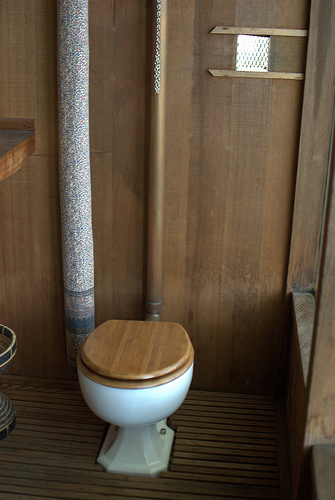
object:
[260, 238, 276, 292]
brown color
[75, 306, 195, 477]
one toilet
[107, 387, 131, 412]
white color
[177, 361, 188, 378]
seat is brown color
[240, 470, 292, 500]
floor is brown color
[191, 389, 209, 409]
made of wood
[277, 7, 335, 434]
window is brown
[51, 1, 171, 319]
two pipe is running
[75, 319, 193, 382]
this is a toilet lid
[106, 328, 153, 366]
lid is brown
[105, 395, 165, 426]
toilet is white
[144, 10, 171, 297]
pipe is brown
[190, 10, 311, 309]
this is a wall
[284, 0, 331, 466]
this is a window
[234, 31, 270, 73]
small glass window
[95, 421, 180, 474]
porcelain base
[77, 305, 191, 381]
toilet seat top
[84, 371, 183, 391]
brown wood panels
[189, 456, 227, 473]
brown wood panels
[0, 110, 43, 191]
wooden shelf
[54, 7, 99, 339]
pipe for tiolet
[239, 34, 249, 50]
window above tiolet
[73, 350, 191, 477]
bowl is white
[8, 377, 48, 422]
this is the floor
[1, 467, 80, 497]
floor is wooden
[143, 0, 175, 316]
this is a pipe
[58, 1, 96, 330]
pipe is metallic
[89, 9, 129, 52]
wall is brown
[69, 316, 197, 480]
sink is closed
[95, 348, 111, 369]
lid is wooden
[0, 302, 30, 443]
this is a pool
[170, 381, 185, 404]
white in color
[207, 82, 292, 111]
wooden wall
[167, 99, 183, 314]
wooden wall is brown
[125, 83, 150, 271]
wall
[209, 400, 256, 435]
floor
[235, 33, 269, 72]
mirror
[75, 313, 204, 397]
toilet seat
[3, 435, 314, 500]
floor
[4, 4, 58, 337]
wall